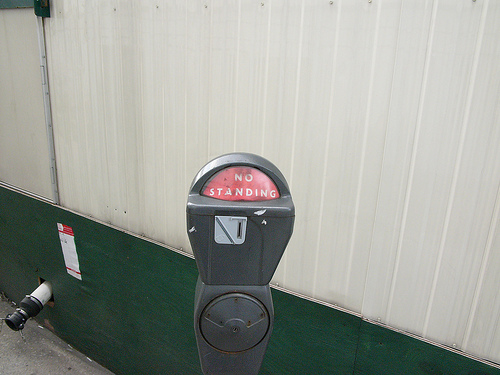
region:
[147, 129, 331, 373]
an expired parking meter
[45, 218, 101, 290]
a red and white sign on wall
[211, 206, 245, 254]
coin slot for parking meter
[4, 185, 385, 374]
a green section of wall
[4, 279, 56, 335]
a tube coming out of wall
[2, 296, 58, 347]
black cap on tube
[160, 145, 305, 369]
a gray and red parking meter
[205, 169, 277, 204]
red and white on parking meter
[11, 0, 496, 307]
white section of wall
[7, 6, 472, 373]
a green and white wall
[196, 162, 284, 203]
No Standing sign in parking meter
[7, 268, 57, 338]
white and black pipe sticking out of wall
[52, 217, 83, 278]
white and red sticker on green board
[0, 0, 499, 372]
white vertical panels on wall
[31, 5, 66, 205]
gray pipe on white wall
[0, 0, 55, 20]
green panels on white wall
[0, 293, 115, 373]
gray concrete in front of green board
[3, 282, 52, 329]
black end of white pipe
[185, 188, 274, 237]
white splotchy marks on parking meter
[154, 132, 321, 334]
parking meter in center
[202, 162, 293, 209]
red no standing sign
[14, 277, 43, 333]
hose coming out of all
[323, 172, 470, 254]
metal white panels on wall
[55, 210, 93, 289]
warning sticker on wall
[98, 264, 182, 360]
green lower portion of wall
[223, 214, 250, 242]
coin slot in meter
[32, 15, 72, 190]
metal rail on wall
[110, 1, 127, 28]
small rivets in wall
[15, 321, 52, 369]
concrete ground by building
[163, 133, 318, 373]
metal parking meter on sidewalk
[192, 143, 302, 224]
red no standing sign on meter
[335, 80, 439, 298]
white wood paneled wall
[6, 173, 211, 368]
white and green painted wall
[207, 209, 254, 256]
grey coin slot on parking meter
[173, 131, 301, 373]
dark grey parking meter with coin slot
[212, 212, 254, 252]
parking meter with coin slot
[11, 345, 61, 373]
grey cement side walk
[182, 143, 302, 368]
parking meter with red sign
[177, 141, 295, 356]
red and grey parking meter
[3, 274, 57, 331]
pipe coming out of hole in outside wall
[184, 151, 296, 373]
meter stating "no standing"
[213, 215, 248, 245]
panel for coin slot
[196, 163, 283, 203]
display window on meter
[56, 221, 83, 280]
red and white label on outside wall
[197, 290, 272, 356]
location where money is removed from meter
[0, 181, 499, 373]
lower wooden exterior wall painted green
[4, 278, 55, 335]
white pipe with black fitting on end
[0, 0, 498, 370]
metal siding on building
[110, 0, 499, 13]
screws securing metal siding to building